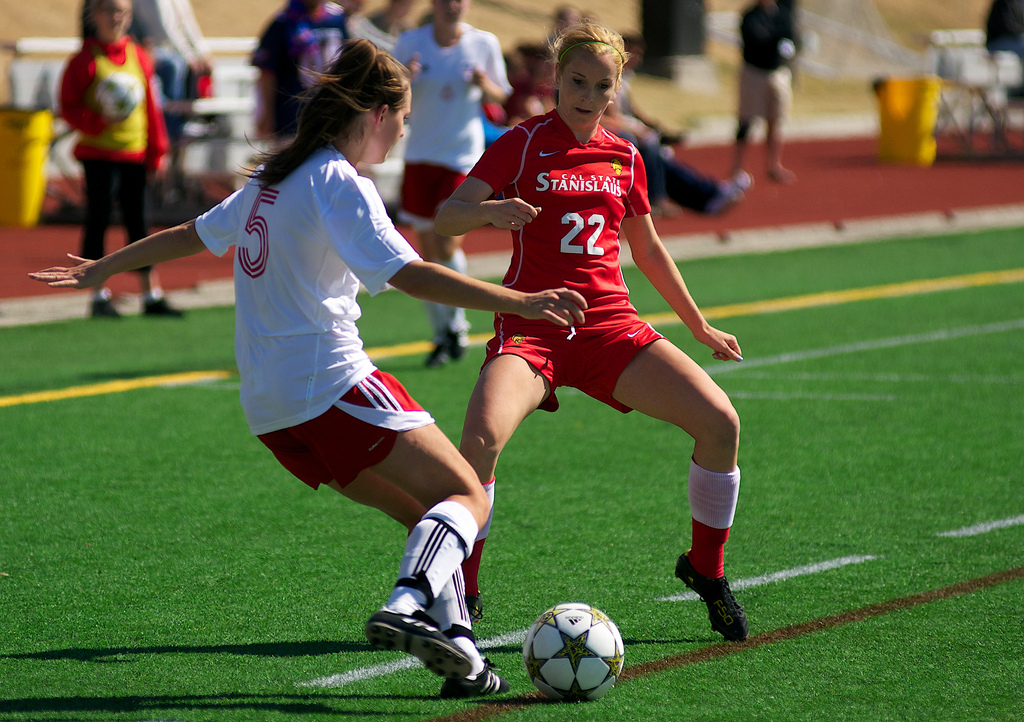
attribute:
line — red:
[844, 552, 980, 650]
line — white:
[778, 520, 892, 609]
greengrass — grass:
[800, 394, 957, 493]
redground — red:
[773, 144, 932, 239]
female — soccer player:
[433, 17, 753, 615]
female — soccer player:
[23, 24, 580, 695]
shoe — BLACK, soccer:
[675, 546, 745, 639]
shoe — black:
[465, 595, 482, 614]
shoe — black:
[361, 599, 469, 682]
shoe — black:
[438, 657, 516, 695]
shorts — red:
[485, 308, 662, 408]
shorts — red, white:
[247, 365, 428, 492]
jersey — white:
[188, 151, 414, 431]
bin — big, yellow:
[870, 71, 940, 164]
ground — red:
[13, 140, 1022, 315]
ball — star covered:
[515, 584, 639, 714]